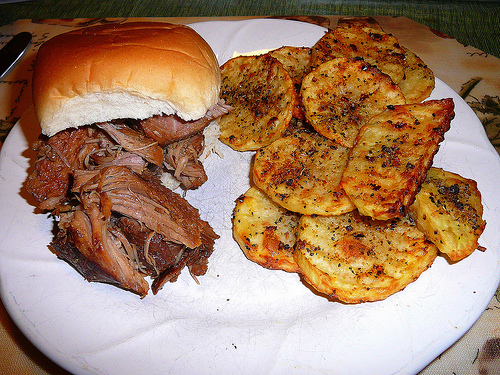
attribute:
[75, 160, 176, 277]
meat — appetizing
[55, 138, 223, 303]
food — piece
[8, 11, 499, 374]
table — in the picture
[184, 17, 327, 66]
plate — pizza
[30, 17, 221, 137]
bread — brown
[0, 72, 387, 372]
plate — white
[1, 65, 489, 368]
dish — in the picture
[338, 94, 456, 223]
potato — in the picture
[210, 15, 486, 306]
chips — brown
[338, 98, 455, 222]
slice — potato, fried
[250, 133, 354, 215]
slice — potato, fried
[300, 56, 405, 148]
slice — potato, fried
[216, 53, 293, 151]
slice — potato, fried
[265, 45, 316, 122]
slice — potato, fried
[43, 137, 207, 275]
pork — sinewy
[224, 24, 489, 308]
strips — delicious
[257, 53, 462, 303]
food — in the picture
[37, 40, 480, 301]
food — piece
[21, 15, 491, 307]
food — piece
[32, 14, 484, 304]
meal — delicious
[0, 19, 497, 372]
plate — white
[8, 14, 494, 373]
white plate — round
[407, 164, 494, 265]
food — piece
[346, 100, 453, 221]
slice — pizza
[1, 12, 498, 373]
furniture — plate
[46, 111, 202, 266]
grilled meat — brown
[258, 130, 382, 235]
food — in the picture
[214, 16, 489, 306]
food — delicious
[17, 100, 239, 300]
food — delicious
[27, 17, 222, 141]
food — delicious